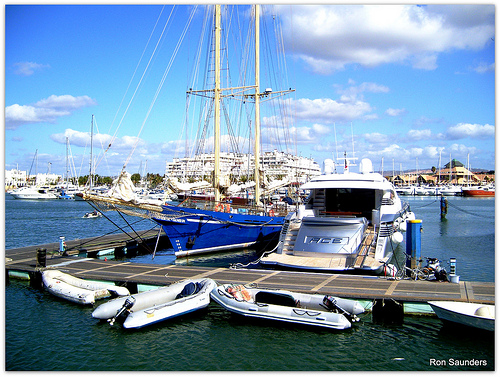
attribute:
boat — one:
[156, 205, 272, 248]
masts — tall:
[204, 3, 273, 217]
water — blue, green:
[24, 190, 493, 282]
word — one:
[297, 227, 348, 247]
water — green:
[30, 325, 498, 375]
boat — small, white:
[433, 292, 498, 330]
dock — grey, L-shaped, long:
[22, 226, 498, 307]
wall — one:
[174, 166, 212, 180]